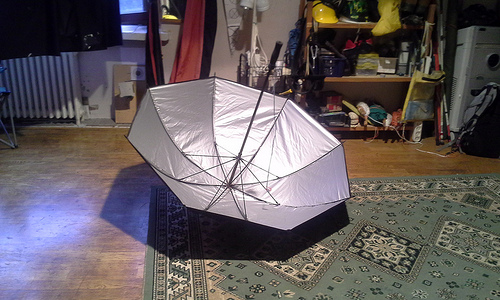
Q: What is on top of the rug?
A: An umbrella.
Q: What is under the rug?
A: The floor.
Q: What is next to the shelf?
A: A washer.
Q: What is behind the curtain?
A: A window.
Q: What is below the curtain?
A: A radiator.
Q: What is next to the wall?
A: A box.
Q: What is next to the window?
A: A wall.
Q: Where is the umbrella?
A: The floor.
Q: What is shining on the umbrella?
A: The light.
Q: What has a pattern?
A: The carpet.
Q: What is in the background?
A: A wooden shelf.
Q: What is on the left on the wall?
A: White radiator.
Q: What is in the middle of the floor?
A: Umbrella.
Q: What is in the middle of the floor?
A: Umbrella.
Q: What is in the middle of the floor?
A: Umbrella.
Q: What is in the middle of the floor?
A: Umbrella.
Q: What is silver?
A: Umbrella.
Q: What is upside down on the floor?
A: Umbrella.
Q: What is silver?
A: Umbrella.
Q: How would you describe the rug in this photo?
A: A green diamond design rug.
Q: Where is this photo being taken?
A: Inside someone's apartment or home.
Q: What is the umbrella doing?
A: Bringing in bad luck because it is indoors.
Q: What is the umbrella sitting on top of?
A: A rug.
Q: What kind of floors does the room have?
A: Hardwood floors.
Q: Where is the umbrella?
A: On the ground.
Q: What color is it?
A: Gray.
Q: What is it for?
A: Rain.